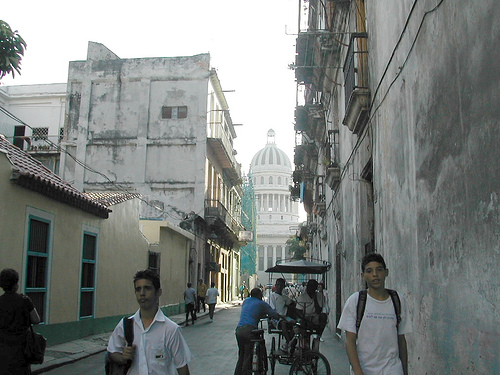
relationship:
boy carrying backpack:
[105, 273, 193, 375] [120, 316, 135, 344]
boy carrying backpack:
[338, 251, 412, 374] [353, 288, 401, 331]